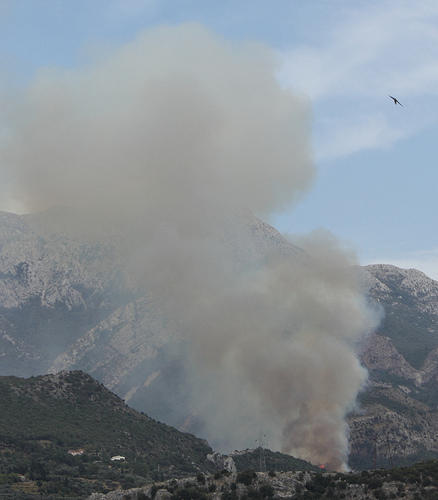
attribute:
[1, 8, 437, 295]
sky — blue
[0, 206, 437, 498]
mountains — large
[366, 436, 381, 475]
power pole — wooden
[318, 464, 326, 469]
flames — orange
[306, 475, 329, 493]
bush — green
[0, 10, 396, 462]
cloud — gray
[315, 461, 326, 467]
flame — orange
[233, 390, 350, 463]
ash — brown, gray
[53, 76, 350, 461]
clouds — white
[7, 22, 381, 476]
cloud — large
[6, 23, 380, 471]
smoke — huge, gray, grey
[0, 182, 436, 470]
mountain — rocky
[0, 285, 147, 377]
patch — dark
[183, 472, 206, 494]
trees — small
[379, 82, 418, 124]
bird — black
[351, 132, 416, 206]
sky — blue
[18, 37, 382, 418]
smoke — large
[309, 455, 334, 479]
lava — red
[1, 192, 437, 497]
hill — rocky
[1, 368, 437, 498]
hill — greenish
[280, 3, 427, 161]
cloud — light colored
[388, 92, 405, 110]
bird — flying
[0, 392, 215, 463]
plants — green